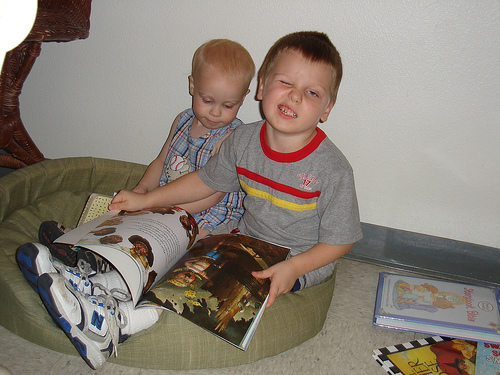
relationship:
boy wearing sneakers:
[10, 30, 366, 339] [13, 239, 123, 373]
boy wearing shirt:
[209, 30, 366, 293] [227, 119, 352, 266]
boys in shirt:
[37, 37, 254, 272] [197, 119, 362, 293]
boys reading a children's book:
[37, 37, 254, 272] [51, 195, 295, 357]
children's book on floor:
[371, 259, 498, 350] [0, 256, 489, 373]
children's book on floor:
[372, 330, 485, 373] [0, 256, 489, 373]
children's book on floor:
[472, 339, 493, 374] [0, 256, 489, 373]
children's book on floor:
[51, 195, 295, 357] [0, 256, 489, 373]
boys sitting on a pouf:
[37, 37, 254, 272] [33, 166, 90, 208]